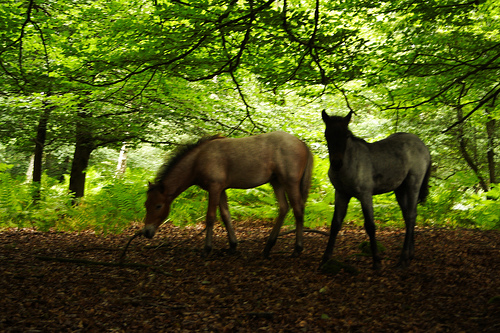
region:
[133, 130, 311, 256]
a horse munching on some leaves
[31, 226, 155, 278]
a stick laying on the dirt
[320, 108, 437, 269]
a pale white horse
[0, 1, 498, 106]
a lush green forest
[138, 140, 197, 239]
a long brown horse neck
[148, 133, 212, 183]
a black horse mane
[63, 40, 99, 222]
a tall black tree trunk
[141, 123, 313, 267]
a brown horse facing sideways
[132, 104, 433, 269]
two horses in the woods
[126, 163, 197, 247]
the head of a horse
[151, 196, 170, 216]
the eye of a horse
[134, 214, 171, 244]
the nose of a horse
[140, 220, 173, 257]
the mouth of a horse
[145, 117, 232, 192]
the main of a horse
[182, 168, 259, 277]
the front legs of a horse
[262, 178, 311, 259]
the back legs of a horse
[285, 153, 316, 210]
the tail of a horse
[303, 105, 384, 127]
the ears of a horse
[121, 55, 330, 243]
a horse near a tree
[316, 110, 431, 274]
A tall skinny grey and black horse.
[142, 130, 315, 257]
A tan and brown horse with it's head down.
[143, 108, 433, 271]
Two horses in a meadow.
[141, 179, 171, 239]
Brown head of a horse that is close to the ground.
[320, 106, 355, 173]
Black head of a horse.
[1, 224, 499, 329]
Brown leaves all over the ground.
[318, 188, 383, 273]
Two front legs of a black and grey horse.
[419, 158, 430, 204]
Black cut tail of a grey and black horse.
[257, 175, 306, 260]
Two back brown legs of a horse.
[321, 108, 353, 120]
Two black ears on a grey and black horse.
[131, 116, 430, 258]
Horses in the field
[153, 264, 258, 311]
Dry leaves on the ground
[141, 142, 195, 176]
Fur on the horse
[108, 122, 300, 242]
A horse grazing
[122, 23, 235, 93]
Leaves on the tree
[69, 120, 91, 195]
A tree trunk in the photo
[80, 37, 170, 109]
Branches in the tree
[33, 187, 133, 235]
Vegetation on the ground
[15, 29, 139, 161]
Trees in the forest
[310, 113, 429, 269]
A horse looking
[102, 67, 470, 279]
two horses in the forest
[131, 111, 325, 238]
the horse on the left is brown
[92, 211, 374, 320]
leaves are on the ground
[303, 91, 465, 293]
the horse on the right is grey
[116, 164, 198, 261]
the head is down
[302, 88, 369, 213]
the horse is looking in the camera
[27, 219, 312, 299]
sticks are on the ground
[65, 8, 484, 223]
trees are surrounding the animals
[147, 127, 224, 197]
the mane is black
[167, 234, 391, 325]
the leaves are brown